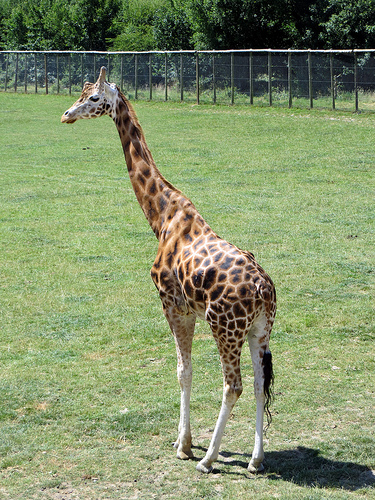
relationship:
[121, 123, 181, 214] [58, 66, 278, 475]
neck of giraffe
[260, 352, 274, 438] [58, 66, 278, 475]
hair of giraffe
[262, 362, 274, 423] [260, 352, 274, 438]
hair of hair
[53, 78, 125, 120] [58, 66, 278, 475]
head of giraffe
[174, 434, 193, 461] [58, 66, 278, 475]
foot of giraffe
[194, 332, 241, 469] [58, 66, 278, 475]
leg of giraffe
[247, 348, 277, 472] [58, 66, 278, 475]
leg of giraffe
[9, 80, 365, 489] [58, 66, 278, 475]
area around giraffe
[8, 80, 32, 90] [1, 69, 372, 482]
wheel on ground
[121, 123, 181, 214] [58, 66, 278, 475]
neck on giraffe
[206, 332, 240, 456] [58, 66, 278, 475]
leg of giraffe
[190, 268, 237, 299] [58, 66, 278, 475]
patches on giraffe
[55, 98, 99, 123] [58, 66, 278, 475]
muzzle of giraffe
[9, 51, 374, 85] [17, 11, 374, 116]
fence in background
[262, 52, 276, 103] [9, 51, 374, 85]
pole on fence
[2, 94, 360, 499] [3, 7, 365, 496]
grass in photo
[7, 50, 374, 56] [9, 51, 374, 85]
bar on fence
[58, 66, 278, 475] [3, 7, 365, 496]
giraffe in photo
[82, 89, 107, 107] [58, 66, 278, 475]
eye of giraffe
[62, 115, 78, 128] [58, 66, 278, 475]
mouth of giraffe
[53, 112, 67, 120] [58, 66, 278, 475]
nose of giraffe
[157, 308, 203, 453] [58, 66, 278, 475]
legs of giraffe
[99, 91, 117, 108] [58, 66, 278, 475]
ear of giraffe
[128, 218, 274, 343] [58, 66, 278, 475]
body of giraffe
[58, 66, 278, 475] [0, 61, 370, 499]
giraffe in area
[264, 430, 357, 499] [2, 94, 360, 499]
shadow on grass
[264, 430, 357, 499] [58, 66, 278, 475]
shadow of giraffe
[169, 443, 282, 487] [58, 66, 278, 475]
hooves of giraffe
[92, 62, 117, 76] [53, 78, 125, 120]
horns on head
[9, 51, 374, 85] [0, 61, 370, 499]
fence along area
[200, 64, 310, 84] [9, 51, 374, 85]
posts attached to fence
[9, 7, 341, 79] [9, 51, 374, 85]
trees behind fence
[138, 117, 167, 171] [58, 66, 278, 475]
mane of giraffe